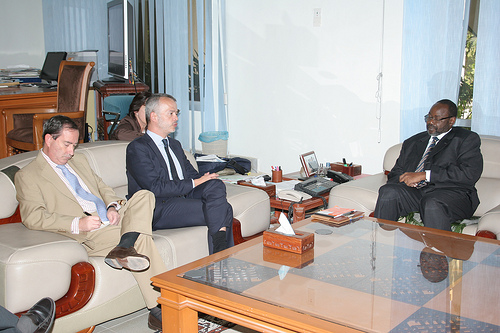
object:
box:
[263, 228, 316, 254]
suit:
[373, 127, 484, 234]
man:
[379, 99, 484, 236]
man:
[126, 92, 241, 252]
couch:
[0, 136, 275, 330]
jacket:
[12, 148, 123, 246]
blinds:
[143, 0, 228, 152]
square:
[150, 210, 499, 332]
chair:
[329, 134, 500, 239]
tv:
[104, 1, 140, 79]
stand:
[92, 78, 149, 143]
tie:
[53, 165, 109, 220]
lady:
[113, 94, 154, 141]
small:
[199, 131, 229, 157]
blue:
[198, 127, 226, 141]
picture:
[305, 154, 317, 173]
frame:
[297, 150, 322, 176]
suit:
[17, 146, 159, 309]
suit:
[124, 132, 236, 255]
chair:
[1, 57, 98, 163]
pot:
[271, 170, 283, 182]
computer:
[20, 51, 69, 88]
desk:
[0, 82, 90, 152]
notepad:
[314, 205, 359, 217]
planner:
[311, 214, 366, 224]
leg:
[180, 179, 230, 251]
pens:
[270, 165, 281, 170]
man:
[16, 111, 160, 330]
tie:
[160, 137, 181, 182]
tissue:
[275, 211, 296, 234]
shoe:
[104, 245, 154, 273]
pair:
[423, 112, 457, 121]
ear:
[149, 112, 156, 123]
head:
[40, 114, 83, 166]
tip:
[33, 296, 58, 309]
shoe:
[21, 296, 56, 333]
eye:
[168, 111, 173, 115]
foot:
[102, 247, 153, 274]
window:
[225, 0, 495, 121]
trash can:
[198, 131, 231, 157]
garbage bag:
[198, 128, 229, 143]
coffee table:
[151, 204, 498, 330]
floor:
[78, 313, 216, 333]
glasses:
[424, 113, 457, 121]